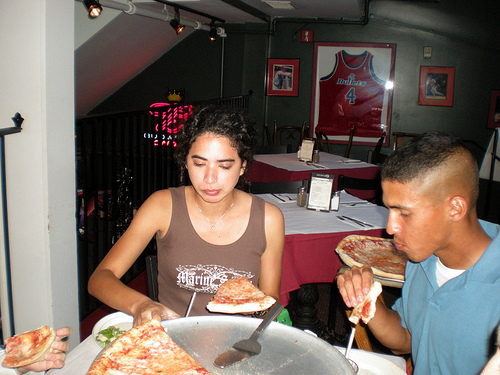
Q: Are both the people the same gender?
A: No, they are both male and female.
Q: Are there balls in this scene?
A: No, there are no balls.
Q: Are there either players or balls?
A: No, there are no balls or players.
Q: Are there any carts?
A: No, there are no carts.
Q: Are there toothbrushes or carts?
A: No, there are no carts or toothbrushes.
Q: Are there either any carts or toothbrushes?
A: No, there are no carts or toothbrushes.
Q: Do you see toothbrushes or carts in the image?
A: No, there are no carts or toothbrushes.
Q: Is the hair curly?
A: Yes, the hair is curly.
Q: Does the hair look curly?
A: Yes, the hair is curly.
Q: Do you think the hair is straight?
A: No, the hair is curly.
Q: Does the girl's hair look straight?
A: No, the hair is curly.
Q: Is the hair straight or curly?
A: The hair is curly.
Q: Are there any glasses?
A: No, there are no glasses.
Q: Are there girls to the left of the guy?
A: Yes, there is a girl to the left of the guy.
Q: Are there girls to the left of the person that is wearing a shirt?
A: Yes, there is a girl to the left of the guy.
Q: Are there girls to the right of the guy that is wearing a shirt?
A: No, the girl is to the left of the guy.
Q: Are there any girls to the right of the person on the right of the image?
A: No, the girl is to the left of the guy.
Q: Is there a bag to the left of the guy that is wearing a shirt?
A: No, there is a girl to the left of the guy.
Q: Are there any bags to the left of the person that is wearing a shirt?
A: No, there is a girl to the left of the guy.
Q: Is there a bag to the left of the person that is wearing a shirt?
A: No, there is a girl to the left of the guy.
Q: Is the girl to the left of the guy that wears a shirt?
A: Yes, the girl is to the left of the guy.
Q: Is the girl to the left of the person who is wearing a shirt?
A: Yes, the girl is to the left of the guy.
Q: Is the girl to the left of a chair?
A: No, the girl is to the left of the guy.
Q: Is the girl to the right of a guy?
A: No, the girl is to the left of a guy.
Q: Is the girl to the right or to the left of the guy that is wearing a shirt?
A: The girl is to the left of the guy.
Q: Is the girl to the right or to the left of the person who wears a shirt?
A: The girl is to the left of the guy.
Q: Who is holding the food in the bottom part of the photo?
A: The girl is holding the pizza.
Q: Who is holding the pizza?
A: The girl is holding the pizza.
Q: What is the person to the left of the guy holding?
A: The girl is holding the pizza.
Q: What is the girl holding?
A: The girl is holding the pizza.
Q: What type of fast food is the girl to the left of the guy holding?
A: The girl is holding the pizza.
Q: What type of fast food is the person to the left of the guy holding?
A: The girl is holding the pizza.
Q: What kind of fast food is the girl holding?
A: The girl is holding the pizza.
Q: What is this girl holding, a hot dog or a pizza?
A: The girl is holding a pizza.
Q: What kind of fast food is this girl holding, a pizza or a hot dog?
A: The girl is holding a pizza.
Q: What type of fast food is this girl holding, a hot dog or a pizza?
A: The girl is holding a pizza.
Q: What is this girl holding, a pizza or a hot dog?
A: The girl is holding a pizza.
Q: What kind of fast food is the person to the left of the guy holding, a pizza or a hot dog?
A: The girl is holding a pizza.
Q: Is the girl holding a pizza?
A: Yes, the girl is holding a pizza.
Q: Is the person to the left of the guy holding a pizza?
A: Yes, the girl is holding a pizza.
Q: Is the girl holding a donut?
A: No, the girl is holding a pizza.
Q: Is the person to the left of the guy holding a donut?
A: No, the girl is holding a pizza.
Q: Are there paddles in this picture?
A: No, there are no paddles.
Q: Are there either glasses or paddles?
A: No, there are no paddles or glasses.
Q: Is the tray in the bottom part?
A: Yes, the tray is in the bottom of the image.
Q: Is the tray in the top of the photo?
A: No, the tray is in the bottom of the image.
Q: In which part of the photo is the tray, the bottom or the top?
A: The tray is in the bottom of the image.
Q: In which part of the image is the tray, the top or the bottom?
A: The tray is in the bottom of the image.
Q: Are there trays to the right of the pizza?
A: Yes, there is a tray to the right of the pizza.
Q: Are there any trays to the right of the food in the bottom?
A: Yes, there is a tray to the right of the pizza.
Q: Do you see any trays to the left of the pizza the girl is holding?
A: No, the tray is to the right of the pizza.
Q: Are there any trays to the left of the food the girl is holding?
A: No, the tray is to the right of the pizza.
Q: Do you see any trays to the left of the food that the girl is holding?
A: No, the tray is to the right of the pizza.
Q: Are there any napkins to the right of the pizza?
A: No, there is a tray to the right of the pizza.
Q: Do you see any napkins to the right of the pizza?
A: No, there is a tray to the right of the pizza.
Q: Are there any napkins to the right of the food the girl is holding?
A: No, there is a tray to the right of the pizza.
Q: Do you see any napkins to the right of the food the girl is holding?
A: No, there is a tray to the right of the pizza.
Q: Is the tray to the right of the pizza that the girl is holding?
A: Yes, the tray is to the right of the pizza.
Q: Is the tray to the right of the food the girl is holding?
A: Yes, the tray is to the right of the pizza.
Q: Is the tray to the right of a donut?
A: No, the tray is to the right of the pizza.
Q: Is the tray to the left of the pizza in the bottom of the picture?
A: No, the tray is to the right of the pizza.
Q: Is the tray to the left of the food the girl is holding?
A: No, the tray is to the right of the pizza.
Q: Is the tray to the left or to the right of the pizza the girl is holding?
A: The tray is to the right of the pizza.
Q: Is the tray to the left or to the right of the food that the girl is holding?
A: The tray is to the right of the pizza.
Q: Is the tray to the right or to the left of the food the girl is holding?
A: The tray is to the right of the pizza.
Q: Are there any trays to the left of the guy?
A: Yes, there is a tray to the left of the guy.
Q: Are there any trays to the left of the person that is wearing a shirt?
A: Yes, there is a tray to the left of the guy.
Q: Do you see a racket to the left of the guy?
A: No, there is a tray to the left of the guy.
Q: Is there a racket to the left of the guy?
A: No, there is a tray to the left of the guy.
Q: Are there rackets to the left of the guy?
A: No, there is a tray to the left of the guy.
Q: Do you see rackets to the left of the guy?
A: No, there is a tray to the left of the guy.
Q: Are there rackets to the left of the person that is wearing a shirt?
A: No, there is a tray to the left of the guy.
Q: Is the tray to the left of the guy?
A: Yes, the tray is to the left of the guy.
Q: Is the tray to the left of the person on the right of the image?
A: Yes, the tray is to the left of the guy.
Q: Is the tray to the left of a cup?
A: No, the tray is to the left of the guy.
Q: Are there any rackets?
A: No, there are no rackets.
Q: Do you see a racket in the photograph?
A: No, there are no rackets.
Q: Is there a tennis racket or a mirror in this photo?
A: No, there are no rackets or mirrors.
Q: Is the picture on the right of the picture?
A: Yes, the picture is on the right of the image.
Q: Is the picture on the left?
A: No, the picture is on the right of the image.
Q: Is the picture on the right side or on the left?
A: The picture is on the right of the image.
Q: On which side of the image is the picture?
A: The picture is on the right of the image.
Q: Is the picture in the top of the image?
A: Yes, the picture is in the top of the image.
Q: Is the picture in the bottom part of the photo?
A: No, the picture is in the top of the image.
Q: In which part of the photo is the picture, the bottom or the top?
A: The picture is in the top of the image.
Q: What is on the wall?
A: The picture is on the wall.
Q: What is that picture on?
A: The picture is on the wall.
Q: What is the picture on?
A: The picture is on the wall.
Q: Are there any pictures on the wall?
A: Yes, there is a picture on the wall.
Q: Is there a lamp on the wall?
A: No, there is a picture on the wall.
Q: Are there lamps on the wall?
A: No, there is a picture on the wall.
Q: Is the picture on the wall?
A: Yes, the picture is on the wall.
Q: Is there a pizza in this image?
A: Yes, there is a pizza.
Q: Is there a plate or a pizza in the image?
A: Yes, there is a pizza.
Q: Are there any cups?
A: No, there are no cups.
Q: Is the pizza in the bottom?
A: Yes, the pizza is in the bottom of the image.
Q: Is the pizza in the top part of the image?
A: No, the pizza is in the bottom of the image.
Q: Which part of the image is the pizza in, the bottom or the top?
A: The pizza is in the bottom of the image.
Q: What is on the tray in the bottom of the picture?
A: The pizza is on the tray.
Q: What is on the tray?
A: The pizza is on the tray.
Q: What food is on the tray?
A: The food is a pizza.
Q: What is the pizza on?
A: The pizza is on the tray.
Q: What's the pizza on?
A: The pizza is on the tray.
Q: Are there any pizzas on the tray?
A: Yes, there is a pizza on the tray.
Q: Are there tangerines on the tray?
A: No, there is a pizza on the tray.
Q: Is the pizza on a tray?
A: Yes, the pizza is on a tray.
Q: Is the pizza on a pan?
A: No, the pizza is on a tray.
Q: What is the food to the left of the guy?
A: The food is a pizza.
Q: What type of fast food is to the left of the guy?
A: The food is a pizza.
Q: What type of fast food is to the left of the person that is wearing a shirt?
A: The food is a pizza.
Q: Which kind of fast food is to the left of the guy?
A: The food is a pizza.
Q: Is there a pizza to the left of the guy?
A: Yes, there is a pizza to the left of the guy.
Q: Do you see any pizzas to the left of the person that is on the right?
A: Yes, there is a pizza to the left of the guy.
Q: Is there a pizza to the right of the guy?
A: No, the pizza is to the left of the guy.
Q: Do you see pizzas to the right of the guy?
A: No, the pizza is to the left of the guy.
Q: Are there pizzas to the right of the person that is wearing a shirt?
A: No, the pizza is to the left of the guy.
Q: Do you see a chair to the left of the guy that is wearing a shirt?
A: No, there is a pizza to the left of the guy.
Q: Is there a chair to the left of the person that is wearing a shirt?
A: No, there is a pizza to the left of the guy.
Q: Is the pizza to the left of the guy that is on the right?
A: Yes, the pizza is to the left of the guy.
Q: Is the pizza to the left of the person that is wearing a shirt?
A: Yes, the pizza is to the left of the guy.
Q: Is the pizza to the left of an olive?
A: No, the pizza is to the left of the guy.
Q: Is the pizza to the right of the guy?
A: No, the pizza is to the left of the guy.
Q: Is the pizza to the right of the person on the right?
A: No, the pizza is to the left of the guy.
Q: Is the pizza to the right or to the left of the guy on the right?
A: The pizza is to the left of the guy.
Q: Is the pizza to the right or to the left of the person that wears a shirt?
A: The pizza is to the left of the guy.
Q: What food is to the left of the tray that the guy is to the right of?
A: The food is a pizza.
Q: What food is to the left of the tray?
A: The food is a pizza.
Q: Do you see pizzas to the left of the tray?
A: Yes, there is a pizza to the left of the tray.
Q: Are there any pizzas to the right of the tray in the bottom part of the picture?
A: No, the pizza is to the left of the tray.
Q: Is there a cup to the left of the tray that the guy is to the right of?
A: No, there is a pizza to the left of the tray.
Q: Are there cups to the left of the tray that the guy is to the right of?
A: No, there is a pizza to the left of the tray.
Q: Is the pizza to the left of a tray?
A: Yes, the pizza is to the left of a tray.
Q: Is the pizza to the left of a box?
A: No, the pizza is to the left of a tray.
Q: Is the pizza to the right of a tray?
A: No, the pizza is to the left of a tray.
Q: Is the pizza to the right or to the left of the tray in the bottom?
A: The pizza is to the left of the tray.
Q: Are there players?
A: No, there are no players.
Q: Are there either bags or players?
A: No, there are no players or bags.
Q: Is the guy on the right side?
A: Yes, the guy is on the right of the image.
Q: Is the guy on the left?
A: No, the guy is on the right of the image.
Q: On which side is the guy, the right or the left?
A: The guy is on the right of the image.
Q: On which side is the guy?
A: The guy is on the right of the image.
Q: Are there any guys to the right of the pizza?
A: Yes, there is a guy to the right of the pizza.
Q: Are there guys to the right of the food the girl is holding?
A: Yes, there is a guy to the right of the pizza.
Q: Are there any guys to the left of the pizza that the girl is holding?
A: No, the guy is to the right of the pizza.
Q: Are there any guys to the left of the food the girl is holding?
A: No, the guy is to the right of the pizza.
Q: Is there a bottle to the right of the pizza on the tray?
A: No, there is a guy to the right of the pizza.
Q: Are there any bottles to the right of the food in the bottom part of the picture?
A: No, there is a guy to the right of the pizza.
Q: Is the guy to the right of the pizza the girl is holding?
A: Yes, the guy is to the right of the pizza.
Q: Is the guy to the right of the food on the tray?
A: Yes, the guy is to the right of the pizza.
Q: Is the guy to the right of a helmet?
A: No, the guy is to the right of the pizza.